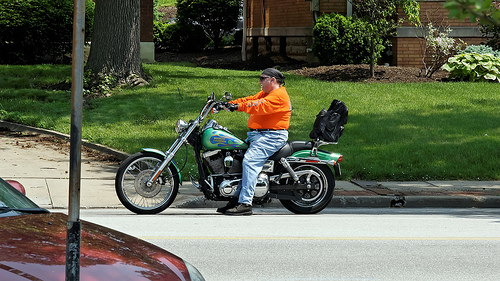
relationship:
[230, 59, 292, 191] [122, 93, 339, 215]
man riding motorcycle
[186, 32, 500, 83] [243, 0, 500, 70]
landscaping near building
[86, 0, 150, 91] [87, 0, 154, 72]
trunk of tree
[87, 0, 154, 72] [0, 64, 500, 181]
tree on grass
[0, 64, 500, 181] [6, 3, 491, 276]
grass in sunlight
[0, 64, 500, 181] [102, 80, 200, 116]
grass in shadow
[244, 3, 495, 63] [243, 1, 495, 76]
building with exterior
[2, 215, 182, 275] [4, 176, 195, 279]
hood of car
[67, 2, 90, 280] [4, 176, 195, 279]
pole in front of car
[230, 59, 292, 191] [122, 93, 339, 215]
man on motorcycle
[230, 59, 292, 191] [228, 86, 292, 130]
man in jacket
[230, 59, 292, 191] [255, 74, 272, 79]
man wearing sunglasses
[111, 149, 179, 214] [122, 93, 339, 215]
wheel of motorcycle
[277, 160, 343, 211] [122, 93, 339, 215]
wheel of motorcycle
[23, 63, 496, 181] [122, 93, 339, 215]
grass behind motorcycle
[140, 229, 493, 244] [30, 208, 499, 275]
line on road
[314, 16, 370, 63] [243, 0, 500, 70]
bush against building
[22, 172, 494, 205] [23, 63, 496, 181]
sidewalk by grass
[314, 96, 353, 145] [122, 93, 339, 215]
bag on motorcycle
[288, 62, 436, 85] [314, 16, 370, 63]
dirt under bush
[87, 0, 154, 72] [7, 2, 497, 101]
tree in background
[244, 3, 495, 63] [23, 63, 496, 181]
building on grass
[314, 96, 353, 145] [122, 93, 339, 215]
backpack on motorcycle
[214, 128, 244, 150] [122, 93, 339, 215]
flames on motorcycle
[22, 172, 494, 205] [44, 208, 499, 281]
sidewalk along road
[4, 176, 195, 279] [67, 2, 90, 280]
car beside pole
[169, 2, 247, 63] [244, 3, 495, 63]
bushes beside building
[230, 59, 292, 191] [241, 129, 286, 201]
man wearing pants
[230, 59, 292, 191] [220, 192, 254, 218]
man wearing boots